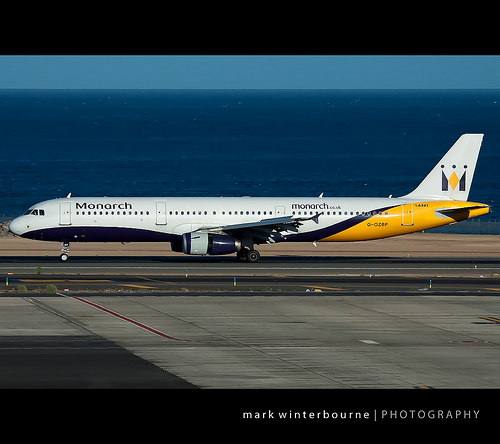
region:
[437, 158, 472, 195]
A SYMBOL OF A CROWN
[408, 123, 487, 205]
THE TAIL OF AN AIRPLANE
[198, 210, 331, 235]
THE WING OF AN AIRPLANE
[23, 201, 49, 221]
AN AIRPLANES FRONT WINDOWS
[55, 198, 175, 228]
TWO AIRPLANE DOORS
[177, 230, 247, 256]
AN AIRPLANES ENGINE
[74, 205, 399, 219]
A ROW OF PASSENGER WINDOWS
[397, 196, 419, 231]
A YELLOW AIRPLANE DOOR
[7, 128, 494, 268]
A BLUE, WHITE AND YELLOW PLANE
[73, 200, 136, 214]
MONARCH WRITTEN ON THE SIDE OF THE PLANE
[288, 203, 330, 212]
monarch on the plane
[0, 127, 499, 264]
blue and yellow plane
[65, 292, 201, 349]
red stripe in the road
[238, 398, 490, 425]
mark winterbourne photography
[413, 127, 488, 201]
tail end of the plane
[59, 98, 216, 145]
dark blue calm water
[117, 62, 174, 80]
dark blue calm sky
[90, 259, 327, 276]
runway with white line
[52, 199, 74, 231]
white door of the plane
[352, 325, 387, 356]
white square on the road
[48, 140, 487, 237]
yellow and white plane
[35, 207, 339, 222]
row of small windows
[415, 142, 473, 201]
yellow logo on tail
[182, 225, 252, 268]
grey stripe on engine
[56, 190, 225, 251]
black stripe on plane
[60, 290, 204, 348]
red line on tarmac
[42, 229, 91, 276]
black and white wheels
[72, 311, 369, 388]
tarmac is light grey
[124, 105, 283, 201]
water is dark blue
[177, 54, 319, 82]
light blue and cloudless sky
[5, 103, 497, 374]
A plane has landed safely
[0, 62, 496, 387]
An airplane is close to the ocean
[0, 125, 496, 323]
A commercial plane is at the airport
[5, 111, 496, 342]
A jetliner is bringing passengers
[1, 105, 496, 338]
An airplane has landed on schedule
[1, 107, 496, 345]
An airplane is taking off very soon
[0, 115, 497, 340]
A plane has landed in the Bahamas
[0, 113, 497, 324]
A plane is taking off from Hawaii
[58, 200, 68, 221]
The door of an airplane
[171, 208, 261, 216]
The windows of an airplane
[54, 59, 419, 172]
dark blue ocean under a light blue sky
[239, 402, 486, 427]
attribute on photo in white and gray letters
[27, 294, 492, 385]
gray runway at an airport next to the ocean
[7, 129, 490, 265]
white, black and yellow jet airplane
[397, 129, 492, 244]
yellow white and black tail on a jet airplane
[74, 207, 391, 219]
cabin windows along the cabin of a plane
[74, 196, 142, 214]
name of airline in black letters on white plane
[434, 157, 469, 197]
yellow and black logo of airline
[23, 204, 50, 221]
front windows of cockpit in a jet airplane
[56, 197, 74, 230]
white front door of a jet airplane